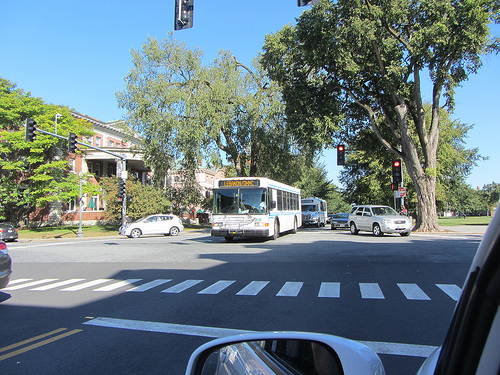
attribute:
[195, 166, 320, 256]
bus — large, here, huge, grey, close, driving, big, moving, turning, black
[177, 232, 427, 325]
road — black, paved, dark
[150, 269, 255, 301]
line — white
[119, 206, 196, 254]
car — below, turning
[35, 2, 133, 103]
sky — light, above, blue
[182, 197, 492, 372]
car — white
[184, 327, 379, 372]
mirror — white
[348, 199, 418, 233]
suv — silver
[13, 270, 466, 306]
lines — painted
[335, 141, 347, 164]
traffic light — red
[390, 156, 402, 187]
traffic light — red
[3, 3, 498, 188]
sky — blue